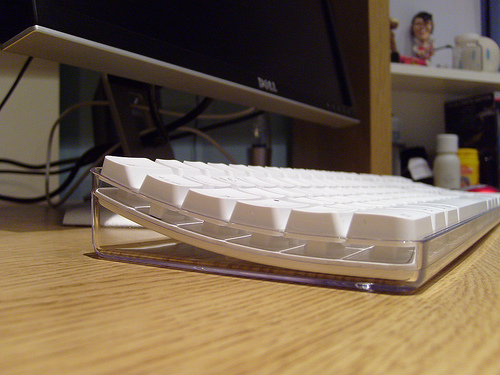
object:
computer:
[0, 0, 361, 227]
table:
[2, 197, 497, 374]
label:
[435, 155, 459, 188]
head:
[410, 10, 435, 41]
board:
[369, 1, 390, 175]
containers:
[432, 134, 462, 190]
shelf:
[288, 1, 495, 177]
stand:
[85, 168, 500, 295]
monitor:
[42, 0, 353, 108]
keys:
[146, 151, 483, 253]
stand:
[59, 74, 175, 227]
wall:
[399, 0, 483, 64]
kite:
[253, 18, 339, 60]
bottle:
[452, 33, 485, 70]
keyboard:
[90, 154, 498, 295]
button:
[348, 212, 434, 240]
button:
[283, 207, 350, 239]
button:
[229, 200, 282, 232]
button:
[183, 188, 228, 225]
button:
[141, 174, 182, 211]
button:
[98, 157, 144, 193]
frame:
[0, 0, 363, 131]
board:
[96, 154, 500, 247]